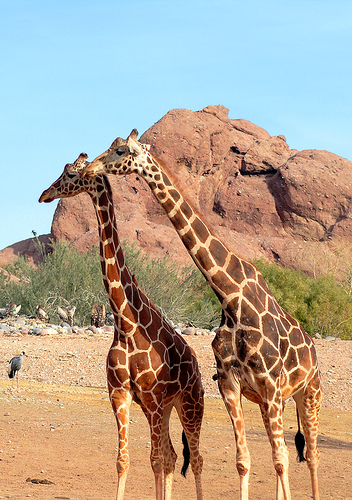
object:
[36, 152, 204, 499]
giraffe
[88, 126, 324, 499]
giraffe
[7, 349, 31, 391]
bird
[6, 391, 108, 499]
soil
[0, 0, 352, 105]
sky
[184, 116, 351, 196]
rock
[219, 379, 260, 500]
leg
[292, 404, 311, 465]
tail